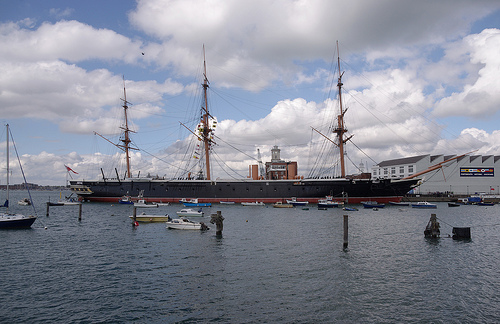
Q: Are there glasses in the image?
A: No, there are no glasses.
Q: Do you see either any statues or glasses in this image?
A: No, there are no glasses or statues.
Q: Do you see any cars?
A: No, there are no cars.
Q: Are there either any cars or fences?
A: No, there are no cars or fences.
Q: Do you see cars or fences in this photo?
A: No, there are no cars or fences.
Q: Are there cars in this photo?
A: No, there are no cars.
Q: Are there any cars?
A: No, there are no cars.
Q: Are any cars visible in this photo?
A: No, there are no cars.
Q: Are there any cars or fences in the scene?
A: No, there are no cars or fences.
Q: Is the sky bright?
A: Yes, the sky is bright.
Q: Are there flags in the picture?
A: Yes, there is a flag.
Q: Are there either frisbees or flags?
A: Yes, there is a flag.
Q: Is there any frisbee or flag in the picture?
A: Yes, there is a flag.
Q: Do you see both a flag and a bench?
A: No, there is a flag but no benches.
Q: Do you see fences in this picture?
A: No, there are no fences.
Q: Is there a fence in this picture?
A: No, there are no fences.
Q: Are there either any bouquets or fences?
A: No, there are no fences or bouquets.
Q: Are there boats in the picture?
A: Yes, there is a boat.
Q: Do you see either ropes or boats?
A: Yes, there is a boat.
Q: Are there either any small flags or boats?
A: Yes, there is a small boat.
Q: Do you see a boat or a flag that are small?
A: Yes, the boat is small.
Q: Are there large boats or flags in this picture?
A: Yes, there is a large boat.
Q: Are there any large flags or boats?
A: Yes, there is a large boat.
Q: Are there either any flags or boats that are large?
A: Yes, the boat is large.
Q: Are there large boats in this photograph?
A: Yes, there is a large boat.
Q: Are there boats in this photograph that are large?
A: Yes, there is a boat that is large.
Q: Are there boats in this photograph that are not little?
A: Yes, there is a large boat.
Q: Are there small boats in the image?
A: Yes, there is a small boat.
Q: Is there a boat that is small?
A: Yes, there is a boat that is small.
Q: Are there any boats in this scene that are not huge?
A: Yes, there is a small boat.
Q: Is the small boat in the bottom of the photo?
A: Yes, the boat is in the bottom of the image.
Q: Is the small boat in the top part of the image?
A: No, the boat is in the bottom of the image.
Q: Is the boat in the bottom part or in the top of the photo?
A: The boat is in the bottom of the image.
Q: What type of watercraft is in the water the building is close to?
A: The watercraft is a boat.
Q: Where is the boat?
A: The boat is in the water.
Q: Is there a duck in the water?
A: No, there is a boat in the water.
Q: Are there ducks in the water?
A: No, there is a boat in the water.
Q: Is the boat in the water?
A: Yes, the boat is in the water.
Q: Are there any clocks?
A: No, there are no clocks.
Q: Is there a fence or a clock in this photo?
A: No, there are no clocks or fences.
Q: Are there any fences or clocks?
A: No, there are no clocks or fences.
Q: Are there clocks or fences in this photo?
A: No, there are no clocks or fences.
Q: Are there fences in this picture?
A: No, there are no fences.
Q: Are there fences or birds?
A: No, there are no fences or birds.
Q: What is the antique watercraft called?
A: The watercraft is a ship.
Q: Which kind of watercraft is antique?
A: The watercraft is a ship.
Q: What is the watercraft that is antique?
A: The watercraft is a ship.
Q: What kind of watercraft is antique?
A: The watercraft is a ship.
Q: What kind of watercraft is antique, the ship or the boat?
A: The ship is antique.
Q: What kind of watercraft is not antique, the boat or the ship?
A: The boat is not antique.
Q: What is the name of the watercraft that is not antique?
A: The watercraft is a boat.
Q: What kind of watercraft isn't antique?
A: The watercraft is a boat.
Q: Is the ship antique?
A: Yes, the ship is antique.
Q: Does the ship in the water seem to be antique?
A: Yes, the ship is antique.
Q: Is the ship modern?
A: No, the ship is antique.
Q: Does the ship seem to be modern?
A: No, the ship is antique.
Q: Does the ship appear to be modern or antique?
A: The ship is antique.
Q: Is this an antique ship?
A: Yes, this is an antique ship.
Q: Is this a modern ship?
A: No, this is an antique ship.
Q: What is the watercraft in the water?
A: The watercraft is a ship.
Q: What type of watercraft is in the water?
A: The watercraft is a ship.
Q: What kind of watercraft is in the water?
A: The watercraft is a ship.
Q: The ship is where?
A: The ship is in the water.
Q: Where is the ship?
A: The ship is in the water.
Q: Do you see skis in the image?
A: No, there are no skis.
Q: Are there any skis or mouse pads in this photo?
A: No, there are no skis or mouse pads.